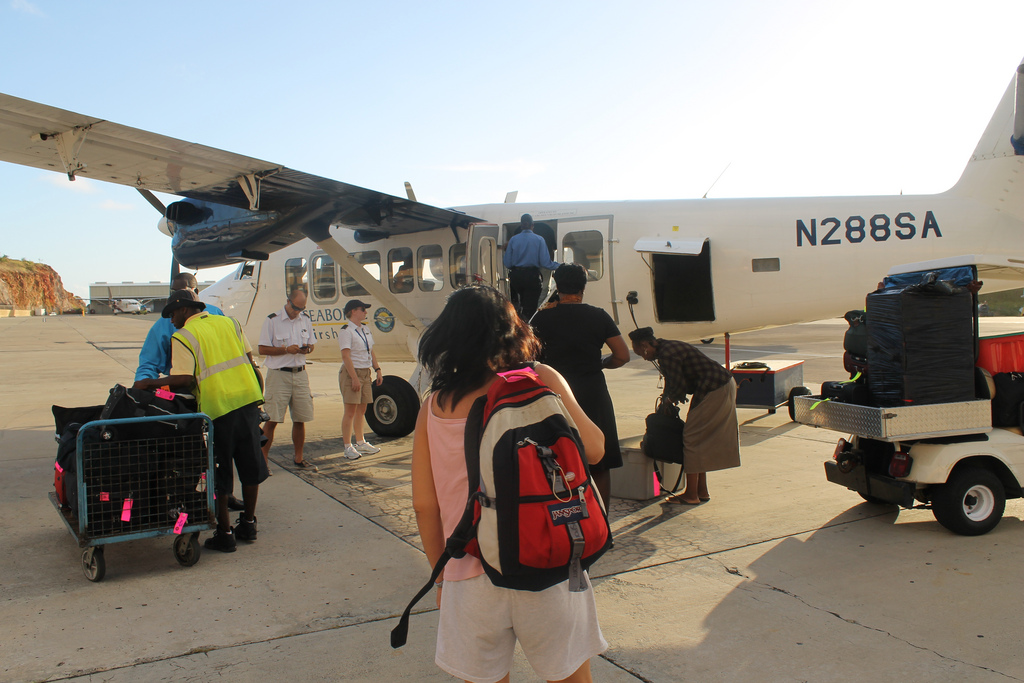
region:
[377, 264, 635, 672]
a person standing on a tarmac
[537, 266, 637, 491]
a person standing on a tarmac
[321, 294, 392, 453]
a person standing on a tarmac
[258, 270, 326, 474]
a person standing on a tarmac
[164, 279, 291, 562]
a person standing on a tarmac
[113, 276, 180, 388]
a person standing on a tarmac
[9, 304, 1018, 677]
a tarmac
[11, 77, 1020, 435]
a plane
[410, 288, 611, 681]
woman wearing pink shirt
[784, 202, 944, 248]
black numbers and letters on the white plane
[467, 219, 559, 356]
open door to the plane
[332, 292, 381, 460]
woman wearing white shirt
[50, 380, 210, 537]
black luggage on the cart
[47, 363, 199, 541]
pink tags on the luggage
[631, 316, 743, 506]
woman wearing brown skirt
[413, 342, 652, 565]
a bag on back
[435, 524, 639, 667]
shorts of the person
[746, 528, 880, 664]
a view of shadow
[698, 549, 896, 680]
shadow on the gorund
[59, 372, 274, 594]
trolley in the road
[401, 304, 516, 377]
hairs of the person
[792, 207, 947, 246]
tail number of the aircraft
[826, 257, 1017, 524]
White Golf cart carrying luggage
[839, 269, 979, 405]
luggage on golf cart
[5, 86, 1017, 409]
white airplane on the tarmac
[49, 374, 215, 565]
blue luggage cart with bags on it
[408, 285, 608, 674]
Woman carrying a red backpack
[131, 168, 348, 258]
Aircraft engine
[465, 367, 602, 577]
red backpack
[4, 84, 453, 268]
airplane wing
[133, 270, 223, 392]
A person is standing up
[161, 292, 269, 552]
A person is standing up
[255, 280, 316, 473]
A person is standing up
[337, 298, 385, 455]
A person is standing up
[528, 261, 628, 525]
A person is standing up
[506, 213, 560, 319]
A person is standing up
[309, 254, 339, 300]
A window on a vehicle.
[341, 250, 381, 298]
A window on a vehicle.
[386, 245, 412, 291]
A window on a vehicle.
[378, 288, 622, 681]
woman wearing white shorts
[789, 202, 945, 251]
black letters and numbers on the plane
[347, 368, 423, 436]
wheel on the white plane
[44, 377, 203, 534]
pink tags on the black luggage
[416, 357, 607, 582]
red black and white backpack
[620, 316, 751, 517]
woman wearing brown skirt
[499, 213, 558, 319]
man wearing blue shirt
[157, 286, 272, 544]
man wearing yellow safety vest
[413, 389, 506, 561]
pink top woman is wearing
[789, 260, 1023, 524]
golf cart next to the plane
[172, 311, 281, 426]
A bright yellow safety vest.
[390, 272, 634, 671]
A person with a backpack on.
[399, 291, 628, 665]
A person with dark brown hair.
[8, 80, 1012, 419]
A small private airplane.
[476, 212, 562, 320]
A person walking onto a plane.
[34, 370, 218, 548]
Luggage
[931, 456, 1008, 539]
wheel belongs to vehicle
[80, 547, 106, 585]
wheel belongs to cart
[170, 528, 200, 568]
wheel belongs to cart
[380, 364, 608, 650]
backpack worn by human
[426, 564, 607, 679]
shorts worn by human